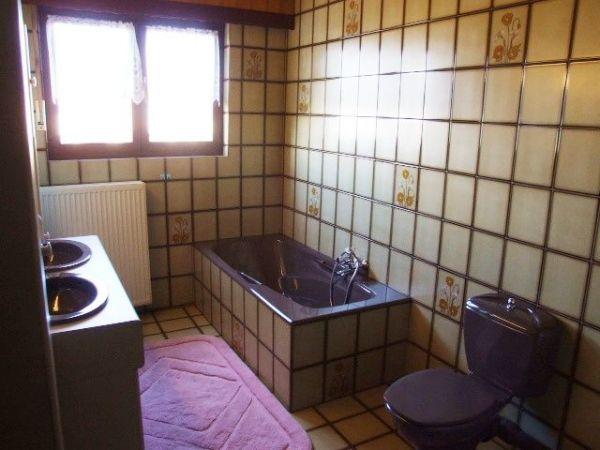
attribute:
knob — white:
[28, 74, 37, 90]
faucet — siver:
[332, 250, 364, 280]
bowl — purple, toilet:
[383, 291, 563, 448]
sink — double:
[40, 232, 141, 383]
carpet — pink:
[137, 333, 313, 448]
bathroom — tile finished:
[5, 3, 596, 448]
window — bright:
[47, 14, 219, 143]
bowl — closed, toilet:
[382, 365, 499, 445]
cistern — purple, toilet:
[464, 292, 560, 396]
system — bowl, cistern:
[383, 290, 564, 448]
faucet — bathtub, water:
[334, 268, 364, 282]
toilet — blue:
[381, 292, 559, 448]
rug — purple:
[137, 333, 311, 447]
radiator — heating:
[36, 182, 154, 306]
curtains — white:
[44, 12, 222, 104]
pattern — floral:
[397, 169, 415, 208]